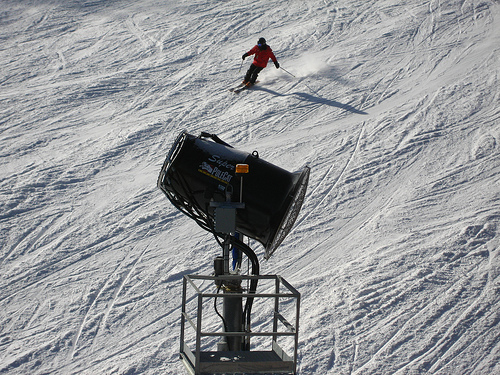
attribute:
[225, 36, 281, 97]
man — skiing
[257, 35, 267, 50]
helmet — black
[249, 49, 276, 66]
jacket — red, thick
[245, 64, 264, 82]
pants — black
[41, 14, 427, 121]
mountain — snow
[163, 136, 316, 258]
light — black, off, huge, dark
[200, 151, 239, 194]
letters — white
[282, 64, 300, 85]
pole — black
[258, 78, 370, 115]
shadow — long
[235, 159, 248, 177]
light — orange, square, small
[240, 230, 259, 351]
cables — thick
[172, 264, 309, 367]
frame — metal, square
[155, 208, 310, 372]
stand — steel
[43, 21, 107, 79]
snow — white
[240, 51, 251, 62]
gloves — black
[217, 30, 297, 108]
person — skiing